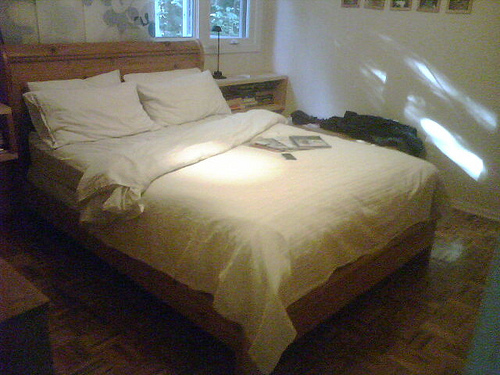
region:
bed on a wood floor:
[4, 42, 449, 371]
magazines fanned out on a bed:
[246, 128, 331, 163]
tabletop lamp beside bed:
[205, 20, 230, 82]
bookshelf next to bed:
[215, 68, 292, 115]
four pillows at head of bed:
[15, 68, 231, 141]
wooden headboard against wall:
[1, 31, 211, 131]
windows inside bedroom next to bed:
[155, 0, 257, 45]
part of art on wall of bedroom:
[337, 2, 479, 21]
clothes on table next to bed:
[290, 97, 430, 150]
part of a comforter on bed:
[63, 137, 340, 226]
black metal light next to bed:
[206, 21, 228, 81]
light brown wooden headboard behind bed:
[1, 35, 206, 215]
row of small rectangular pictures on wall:
[336, 0, 478, 17]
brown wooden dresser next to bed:
[0, 240, 62, 374]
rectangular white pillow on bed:
[19, 77, 163, 150]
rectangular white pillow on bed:
[131, 67, 234, 128]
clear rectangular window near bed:
[149, 0, 204, 45]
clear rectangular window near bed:
[206, 0, 258, 45]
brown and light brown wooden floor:
[0, 160, 498, 374]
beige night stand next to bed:
[204, 67, 290, 119]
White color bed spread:
[157, 130, 248, 235]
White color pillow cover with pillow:
[28, 72, 217, 122]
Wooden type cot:
[81, 227, 195, 313]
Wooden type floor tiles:
[373, 314, 438, 374]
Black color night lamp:
[212, 21, 234, 81]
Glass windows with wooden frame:
[159, 0, 249, 35]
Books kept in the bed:
[245, 121, 335, 163]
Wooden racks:
[231, 68, 301, 109]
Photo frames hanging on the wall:
[334, 0, 489, 27]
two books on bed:
[254, 119, 320, 157]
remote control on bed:
[272, 142, 308, 159]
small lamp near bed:
[198, 20, 241, 85]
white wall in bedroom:
[356, 16, 467, 104]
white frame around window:
[145, 0, 239, 41]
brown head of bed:
[14, 32, 197, 90]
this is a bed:
[5, 30, 470, 369]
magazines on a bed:
[227, 121, 352, 173]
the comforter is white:
[60, 98, 472, 359]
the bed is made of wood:
[7, 38, 482, 353]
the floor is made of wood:
[15, 179, 493, 368]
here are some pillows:
[7, 58, 244, 153]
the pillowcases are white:
[14, 55, 255, 142]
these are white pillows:
[5, 63, 269, 143]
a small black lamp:
[194, 6, 243, 86]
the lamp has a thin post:
[204, 15, 233, 82]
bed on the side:
[30, 39, 472, 373]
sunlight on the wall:
[363, 40, 498, 200]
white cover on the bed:
[80, 102, 464, 374]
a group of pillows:
[23, 48, 233, 145]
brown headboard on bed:
[8, 29, 200, 104]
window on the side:
[145, 0, 262, 50]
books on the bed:
[252, 122, 330, 150]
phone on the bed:
[269, 140, 304, 167]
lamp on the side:
[209, 18, 230, 88]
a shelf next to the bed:
[213, 70, 300, 110]